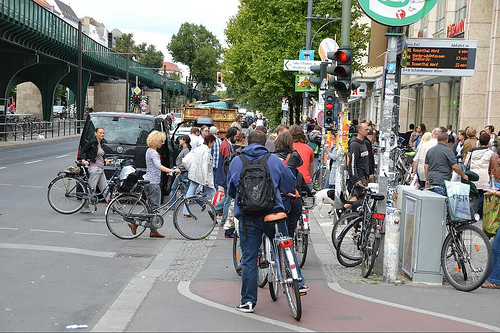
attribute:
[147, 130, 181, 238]
woman — walking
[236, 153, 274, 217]
backpack — black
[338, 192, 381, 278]
bike — leaning, pink, blue, orange, parked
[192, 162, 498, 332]
sidewalk — gray, crowded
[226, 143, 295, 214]
sweatshirt — blue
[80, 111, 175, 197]
car — black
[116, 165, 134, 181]
dog — white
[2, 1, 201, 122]
bridge — green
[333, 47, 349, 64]
light — red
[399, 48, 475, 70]
sign — black, green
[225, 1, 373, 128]
tree — brown, large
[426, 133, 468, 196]
man — old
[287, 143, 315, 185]
shirt — red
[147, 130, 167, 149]
hair — blonde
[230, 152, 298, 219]
person — sitting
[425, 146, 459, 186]
shirt — grey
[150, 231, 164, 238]
boot — brown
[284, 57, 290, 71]
arrow — blue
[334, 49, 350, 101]
traffic light — red